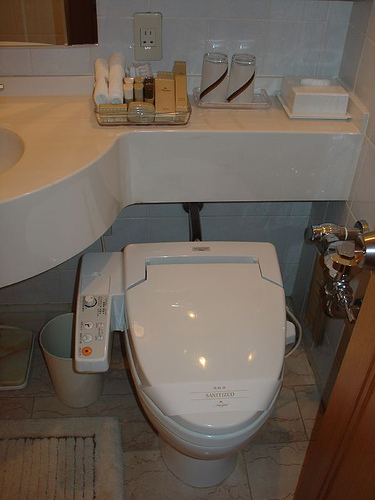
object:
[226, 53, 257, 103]
glass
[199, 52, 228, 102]
glass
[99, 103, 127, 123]
soap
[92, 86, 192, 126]
basket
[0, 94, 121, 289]
edge of sink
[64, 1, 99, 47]
door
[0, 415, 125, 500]
edge of mat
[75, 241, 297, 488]
part of toilet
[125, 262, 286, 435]
part of toilet seat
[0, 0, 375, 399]
edge of wall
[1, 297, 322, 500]
part of floor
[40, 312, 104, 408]
trash can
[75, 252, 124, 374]
white strip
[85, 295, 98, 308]
control knobs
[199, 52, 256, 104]
two water glasses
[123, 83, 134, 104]
bottles of shampoo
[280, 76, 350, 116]
tissue box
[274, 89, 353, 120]
tray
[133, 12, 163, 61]
electrical outlet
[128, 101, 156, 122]
bar of soap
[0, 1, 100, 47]
edge of mirror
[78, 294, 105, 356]
buttons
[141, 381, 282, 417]
paper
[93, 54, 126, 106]
hand towels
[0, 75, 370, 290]
counter top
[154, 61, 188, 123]
paper towel containe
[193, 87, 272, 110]
tray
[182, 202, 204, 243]
chrome plumbing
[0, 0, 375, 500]
bathroom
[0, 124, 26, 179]
bathroom sink basin